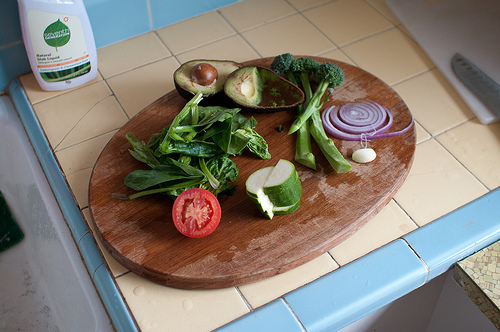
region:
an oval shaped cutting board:
[87, 52, 416, 289]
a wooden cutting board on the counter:
[85, 53, 418, 289]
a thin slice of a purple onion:
[321, 98, 414, 138]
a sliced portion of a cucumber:
[244, 157, 302, 218]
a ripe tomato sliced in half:
[172, 185, 222, 237]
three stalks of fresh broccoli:
[272, 52, 352, 173]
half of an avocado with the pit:
[172, 58, 241, 105]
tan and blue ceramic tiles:
[7, 0, 498, 331]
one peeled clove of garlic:
[350, 146, 375, 161]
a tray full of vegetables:
[85, 53, 416, 290]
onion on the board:
[315, 101, 394, 138]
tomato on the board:
[165, 197, 214, 237]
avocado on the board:
[175, 64, 231, 91]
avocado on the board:
[235, 73, 261, 113]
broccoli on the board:
[295, 55, 317, 68]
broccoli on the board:
[323, 70, 346, 85]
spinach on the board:
[136, 157, 158, 204]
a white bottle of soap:
[16, 0, 105, 98]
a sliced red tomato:
[171, 185, 222, 233]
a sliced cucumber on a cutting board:
[239, 157, 302, 222]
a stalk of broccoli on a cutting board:
[274, 32, 354, 177]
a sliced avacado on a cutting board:
[171, 56, 291, 116]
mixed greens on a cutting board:
[138, 100, 246, 193]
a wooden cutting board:
[86, 52, 427, 289]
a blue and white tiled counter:
[7, 0, 484, 325]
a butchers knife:
[446, 48, 496, 118]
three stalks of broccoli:
[269, 50, 353, 176]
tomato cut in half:
[169, 185, 222, 240]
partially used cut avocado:
[171, 56, 308, 116]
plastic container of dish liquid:
[15, 0, 100, 95]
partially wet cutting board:
[86, 51, 420, 291]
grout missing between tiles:
[398, 233, 430, 289]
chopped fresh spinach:
[123, 88, 273, 200]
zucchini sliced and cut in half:
[243, 157, 305, 221]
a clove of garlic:
[351, 146, 378, 164]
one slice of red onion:
[319, 97, 414, 141]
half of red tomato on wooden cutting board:
[166, 183, 226, 243]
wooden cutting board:
[77, 39, 416, 296]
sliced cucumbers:
[242, 149, 306, 220]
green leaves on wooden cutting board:
[117, 85, 272, 204]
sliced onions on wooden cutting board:
[321, 88, 419, 146]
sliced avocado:
[163, 47, 304, 118]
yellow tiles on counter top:
[17, 1, 498, 329]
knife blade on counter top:
[442, 43, 499, 124]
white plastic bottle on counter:
[16, 1, 108, 97]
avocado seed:
[187, 57, 221, 89]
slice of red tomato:
[170, 186, 220, 236]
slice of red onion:
[322, 101, 412, 138]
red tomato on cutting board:
[165, 185, 230, 242]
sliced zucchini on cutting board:
[233, 156, 302, 226]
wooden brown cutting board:
[80, 47, 416, 284]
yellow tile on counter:
[94, 57, 191, 111]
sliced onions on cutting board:
[313, 95, 417, 142]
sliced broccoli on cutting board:
[270, 41, 357, 181]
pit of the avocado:
[188, 64, 223, 85]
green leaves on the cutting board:
[114, 87, 270, 199]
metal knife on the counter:
[437, 48, 499, 119]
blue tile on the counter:
[271, 228, 426, 330]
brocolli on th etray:
[282, 45, 352, 149]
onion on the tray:
[332, 93, 393, 152]